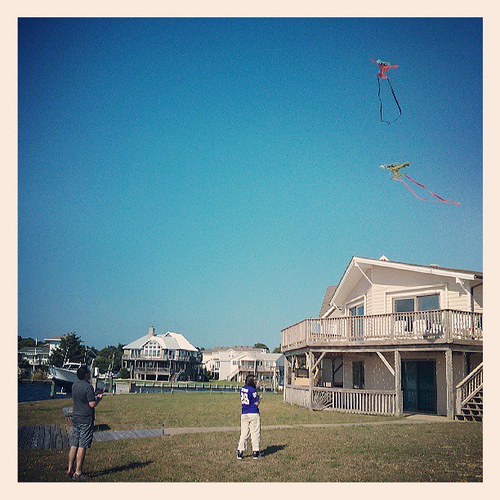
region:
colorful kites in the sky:
[352, 48, 471, 233]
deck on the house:
[331, 319, 405, 344]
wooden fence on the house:
[314, 388, 396, 415]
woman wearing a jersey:
[225, 361, 280, 466]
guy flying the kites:
[60, 360, 112, 479]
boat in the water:
[46, 360, 73, 402]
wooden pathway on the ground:
[107, 426, 172, 443]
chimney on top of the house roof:
[144, 321, 160, 335]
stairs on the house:
[462, 398, 482, 426]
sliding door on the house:
[400, 363, 437, 415]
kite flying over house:
[360, 34, 410, 137]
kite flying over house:
[370, 151, 481, 227]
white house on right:
[269, 271, 486, 422]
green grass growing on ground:
[141, 416, 422, 491]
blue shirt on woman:
[230, 378, 261, 415]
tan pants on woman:
[241, 415, 256, 440]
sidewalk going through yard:
[156, 412, 417, 441]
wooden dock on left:
[1, 420, 151, 457]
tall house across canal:
[127, 334, 190, 380]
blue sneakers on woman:
[235, 445, 261, 462]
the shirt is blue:
[238, 387, 265, 412]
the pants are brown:
[241, 416, 262, 452]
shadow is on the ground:
[266, 440, 285, 454]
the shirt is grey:
[68, 381, 100, 424]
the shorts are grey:
[64, 422, 95, 449]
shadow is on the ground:
[108, 454, 160, 478]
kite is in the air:
[373, 152, 459, 217]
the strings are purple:
[399, 179, 460, 207]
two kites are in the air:
[361, 52, 468, 219]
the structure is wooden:
[273, 273, 483, 416]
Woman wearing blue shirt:
[226, 367, 284, 472]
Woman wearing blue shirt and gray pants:
[227, 372, 282, 475]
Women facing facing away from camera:
[228, 373, 290, 465]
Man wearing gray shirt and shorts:
[60, 359, 109, 480]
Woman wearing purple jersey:
[230, 368, 277, 475]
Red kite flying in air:
[356, 46, 410, 137]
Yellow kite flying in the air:
[366, 149, 463, 228]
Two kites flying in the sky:
[351, 35, 466, 232]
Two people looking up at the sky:
[47, 360, 298, 479]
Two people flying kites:
[32, 47, 462, 475]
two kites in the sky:
[339, 54, 465, 297]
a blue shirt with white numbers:
[226, 372, 265, 423]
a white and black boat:
[43, 352, 126, 409]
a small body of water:
[20, 367, 237, 404]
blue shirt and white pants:
[228, 377, 313, 468]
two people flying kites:
[42, 335, 365, 480]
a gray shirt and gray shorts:
[61, 372, 141, 451]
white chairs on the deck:
[361, 308, 466, 358]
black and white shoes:
[226, 438, 289, 483]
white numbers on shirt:
[238, 387, 255, 407]